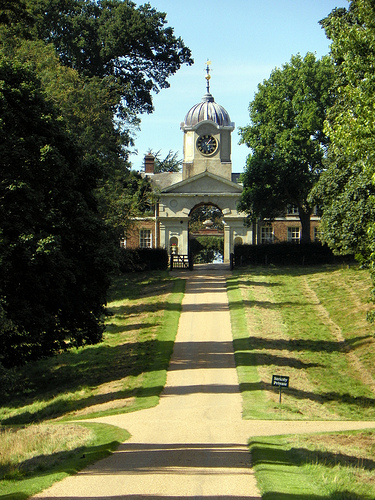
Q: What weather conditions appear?
A: It is clear.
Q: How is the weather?
A: It is clear.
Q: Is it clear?
A: Yes, it is clear.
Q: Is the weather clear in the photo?
A: Yes, it is clear.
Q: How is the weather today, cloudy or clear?
A: It is clear.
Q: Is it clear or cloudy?
A: It is clear.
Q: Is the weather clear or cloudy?
A: It is clear.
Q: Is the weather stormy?
A: No, it is clear.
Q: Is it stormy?
A: No, it is clear.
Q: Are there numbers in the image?
A: Yes, there are numbers.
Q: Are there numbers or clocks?
A: Yes, there are numbers.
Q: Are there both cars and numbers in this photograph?
A: No, there are numbers but no cars.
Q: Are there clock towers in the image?
A: Yes, there is a clock tower.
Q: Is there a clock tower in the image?
A: Yes, there is a clock tower.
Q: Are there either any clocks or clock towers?
A: Yes, there is a clock tower.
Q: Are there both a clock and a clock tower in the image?
A: Yes, there are both a clock tower and a clock.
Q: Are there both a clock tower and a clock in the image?
A: Yes, there are both a clock tower and a clock.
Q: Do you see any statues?
A: No, there are no statues.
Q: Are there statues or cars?
A: No, there are no statues or cars.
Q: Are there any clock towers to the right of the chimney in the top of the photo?
A: Yes, there is a clock tower to the right of the chimney.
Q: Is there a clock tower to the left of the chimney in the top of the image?
A: No, the clock tower is to the right of the chimney.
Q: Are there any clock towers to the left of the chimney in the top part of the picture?
A: No, the clock tower is to the right of the chimney.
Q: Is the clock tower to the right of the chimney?
A: Yes, the clock tower is to the right of the chimney.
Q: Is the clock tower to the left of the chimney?
A: No, the clock tower is to the right of the chimney.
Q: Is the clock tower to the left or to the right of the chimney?
A: The clock tower is to the right of the chimney.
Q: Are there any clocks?
A: Yes, there is a clock.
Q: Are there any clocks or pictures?
A: Yes, there is a clock.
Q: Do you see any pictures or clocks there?
A: Yes, there is a clock.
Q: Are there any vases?
A: No, there are no vases.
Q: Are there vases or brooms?
A: No, there are no vases or brooms.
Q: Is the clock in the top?
A: Yes, the clock is in the top of the image.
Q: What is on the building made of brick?
A: The clock is on the building.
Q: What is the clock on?
A: The clock is on the building.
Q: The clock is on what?
A: The clock is on the building.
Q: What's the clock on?
A: The clock is on the building.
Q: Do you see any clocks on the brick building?
A: Yes, there is a clock on the building.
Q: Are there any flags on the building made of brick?
A: No, there is a clock on the building.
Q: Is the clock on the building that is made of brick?
A: Yes, the clock is on the building.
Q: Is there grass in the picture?
A: Yes, there is grass.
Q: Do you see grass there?
A: Yes, there is grass.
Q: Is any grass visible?
A: Yes, there is grass.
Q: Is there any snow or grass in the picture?
A: Yes, there is grass.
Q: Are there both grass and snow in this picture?
A: No, there is grass but no snow.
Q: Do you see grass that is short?
A: Yes, there is short grass.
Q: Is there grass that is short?
A: Yes, there is grass that is short.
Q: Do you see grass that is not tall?
A: Yes, there is short grass.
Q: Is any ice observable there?
A: No, there is no ice.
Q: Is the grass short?
A: Yes, the grass is short.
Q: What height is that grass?
A: The grass is short.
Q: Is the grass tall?
A: No, the grass is short.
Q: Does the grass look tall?
A: No, the grass is short.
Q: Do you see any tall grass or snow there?
A: No, there is grass but it is short.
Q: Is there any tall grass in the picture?
A: No, there is grass but it is short.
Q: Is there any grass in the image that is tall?
A: No, there is grass but it is short.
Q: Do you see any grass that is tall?
A: No, there is grass but it is short.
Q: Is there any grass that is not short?
A: No, there is grass but it is short.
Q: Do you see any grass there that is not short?
A: No, there is grass but it is short.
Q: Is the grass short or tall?
A: The grass is short.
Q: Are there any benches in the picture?
A: No, there are no benches.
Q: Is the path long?
A: Yes, the path is long.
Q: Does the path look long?
A: Yes, the path is long.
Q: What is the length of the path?
A: The path is long.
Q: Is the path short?
A: No, the path is long.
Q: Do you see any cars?
A: No, there are no cars.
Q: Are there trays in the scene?
A: No, there are no trays.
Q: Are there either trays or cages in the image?
A: No, there are no trays or cages.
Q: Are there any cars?
A: No, there are no cars.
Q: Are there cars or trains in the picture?
A: No, there are no cars or trains.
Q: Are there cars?
A: No, there are no cars.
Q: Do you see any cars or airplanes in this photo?
A: No, there are no cars or airplanes.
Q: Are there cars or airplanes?
A: No, there are no cars or airplanes.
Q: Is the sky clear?
A: Yes, the sky is clear.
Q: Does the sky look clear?
A: Yes, the sky is clear.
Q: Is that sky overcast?
A: No, the sky is clear.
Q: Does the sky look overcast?
A: No, the sky is clear.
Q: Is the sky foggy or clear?
A: The sky is clear.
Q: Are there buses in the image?
A: No, there are no buses.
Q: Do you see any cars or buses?
A: No, there are no buses or cars.